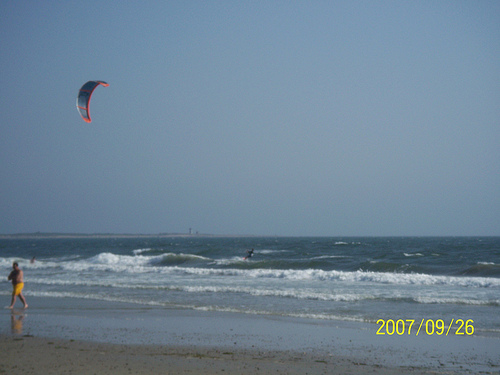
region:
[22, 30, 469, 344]
this is an outdoor setting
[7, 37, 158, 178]
this is kite flying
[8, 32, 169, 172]
the kite is flying on the wind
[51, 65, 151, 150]
the kite is orange and blue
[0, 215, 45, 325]
this is a person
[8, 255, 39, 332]
the person is walking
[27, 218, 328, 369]
this is along a coast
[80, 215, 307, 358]
this is at a beach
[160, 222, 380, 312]
this is an ocean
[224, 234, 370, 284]
the ocean is dark blue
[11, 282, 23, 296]
The man is wearing yellow shorts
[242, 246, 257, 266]
Man is surfing in the ocean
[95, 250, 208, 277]
Waves on the ocean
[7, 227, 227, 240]
Land in the distance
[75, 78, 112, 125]
The kite is in the sky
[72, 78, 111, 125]
The kite is red and blue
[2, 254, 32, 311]
The man is flying a kite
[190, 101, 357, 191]
The blue sky is hazy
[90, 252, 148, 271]
The waves are white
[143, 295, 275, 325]
Water rolling in on the sand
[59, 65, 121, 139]
blue and red kite in the sky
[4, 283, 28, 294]
man wearing yellow shorts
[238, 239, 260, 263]
person para sailing in the water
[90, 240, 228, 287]
waves crashing in the ocean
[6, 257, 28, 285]
man not wearing a shirt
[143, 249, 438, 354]
water washing up on the beach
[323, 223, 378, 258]
waves crashing in the ocean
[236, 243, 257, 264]
person in the water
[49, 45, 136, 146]
object in the air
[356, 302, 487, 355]
date in bottom right corner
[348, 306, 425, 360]
year in bottom right corner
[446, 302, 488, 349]
the number 26 in bottom right corner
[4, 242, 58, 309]
person on the beach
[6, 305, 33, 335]
reflection of a person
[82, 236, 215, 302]
wave approaching the shore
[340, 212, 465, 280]
water in the background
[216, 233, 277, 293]
person in the water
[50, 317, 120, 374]
footprints on the ground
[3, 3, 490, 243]
A blue sky without clouds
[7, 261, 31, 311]
Man in yellow trunks walking on the beach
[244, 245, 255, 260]
A surfer in the ocean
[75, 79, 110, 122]
A kite in the sky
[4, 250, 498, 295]
Waves crashing against the shore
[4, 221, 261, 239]
Land in the distances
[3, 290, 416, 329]
Water sliding along the shore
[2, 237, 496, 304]
Blue water of the ocean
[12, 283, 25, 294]
Yellow trunks on a man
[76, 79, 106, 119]
A blue kite in the air